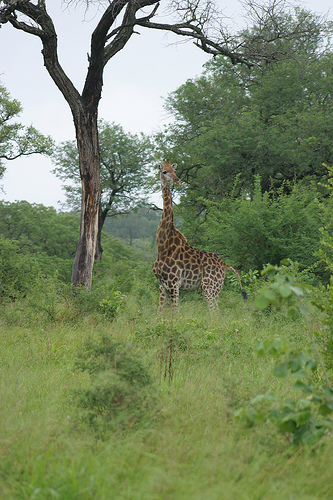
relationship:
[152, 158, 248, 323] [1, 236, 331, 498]
giraffe in field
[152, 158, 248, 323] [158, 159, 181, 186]
giraffe has head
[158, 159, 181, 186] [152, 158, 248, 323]
head on giraffe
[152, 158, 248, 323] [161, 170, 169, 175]
giraffe has eye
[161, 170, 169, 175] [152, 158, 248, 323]
eye on giraffe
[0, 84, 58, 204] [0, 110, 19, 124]
tree has branch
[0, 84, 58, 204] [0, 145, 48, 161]
tree has branch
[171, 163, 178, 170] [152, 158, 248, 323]
ear on giraffe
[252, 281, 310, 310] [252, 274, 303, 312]
leaves on shrub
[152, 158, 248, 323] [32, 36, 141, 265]
giraffe standing near tree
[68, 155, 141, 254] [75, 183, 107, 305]
tree trunk with bark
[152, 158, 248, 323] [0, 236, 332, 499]
giraffe in grass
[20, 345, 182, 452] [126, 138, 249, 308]
grasses by giraffe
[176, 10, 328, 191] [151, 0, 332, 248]
leaves on a tree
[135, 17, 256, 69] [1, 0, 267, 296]
branch on a tree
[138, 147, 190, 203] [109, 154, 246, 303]
head of a giraffe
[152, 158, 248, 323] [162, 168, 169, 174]
giraffe has eye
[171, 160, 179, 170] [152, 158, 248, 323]
ear of a giraffe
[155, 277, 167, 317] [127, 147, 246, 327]
leg of a giraffe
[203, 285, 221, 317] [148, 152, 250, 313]
leg of a giraffe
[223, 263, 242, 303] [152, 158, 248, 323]
tail of a giraffe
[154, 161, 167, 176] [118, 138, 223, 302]
ear of giraffe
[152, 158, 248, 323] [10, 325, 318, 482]
giraffe in field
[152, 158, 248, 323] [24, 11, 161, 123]
giraffe in front of tree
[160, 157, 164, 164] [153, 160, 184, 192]
horn on top of head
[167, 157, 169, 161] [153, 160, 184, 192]
horn on top of head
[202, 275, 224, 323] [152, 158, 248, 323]
back feet of giraffe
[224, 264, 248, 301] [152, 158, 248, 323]
tail of giraffe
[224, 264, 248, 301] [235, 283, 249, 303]
tail with tuft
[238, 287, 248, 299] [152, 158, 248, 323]
turf of giraffe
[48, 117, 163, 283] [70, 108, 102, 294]
small tree behind tree trunk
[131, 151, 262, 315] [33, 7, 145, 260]
giraffe on tree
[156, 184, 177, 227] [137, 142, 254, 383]
neck of giraffe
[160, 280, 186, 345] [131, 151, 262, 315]
leg of giraffe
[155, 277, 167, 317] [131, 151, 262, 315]
leg of giraffe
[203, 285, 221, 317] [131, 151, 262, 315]
leg of giraffe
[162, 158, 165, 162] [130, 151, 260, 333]
horn of giraffe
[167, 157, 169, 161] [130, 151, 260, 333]
horn of giraffe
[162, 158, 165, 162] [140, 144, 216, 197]
horn of giraffe